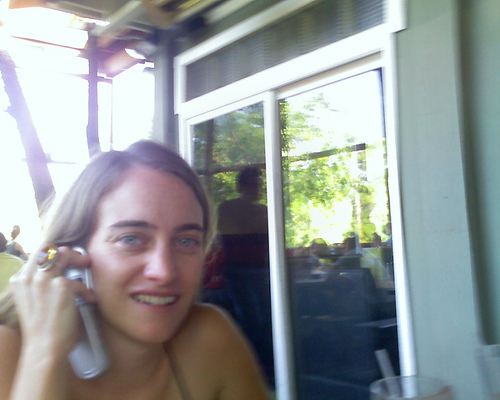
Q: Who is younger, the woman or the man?
A: The woman is younger than the man.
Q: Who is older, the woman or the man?
A: The man is older than the woman.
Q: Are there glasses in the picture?
A: No, there are no glasses.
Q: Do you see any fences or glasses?
A: No, there are no glasses or fences.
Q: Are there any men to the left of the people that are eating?
A: Yes, there is a man to the left of the people.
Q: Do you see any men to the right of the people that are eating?
A: No, the man is to the left of the people.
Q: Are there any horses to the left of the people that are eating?
A: No, there is a man to the left of the people.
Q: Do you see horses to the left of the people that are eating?
A: No, there is a man to the left of the people.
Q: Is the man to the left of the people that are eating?
A: Yes, the man is to the left of the people.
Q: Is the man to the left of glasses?
A: No, the man is to the left of the people.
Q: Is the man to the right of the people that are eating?
A: No, the man is to the left of the people.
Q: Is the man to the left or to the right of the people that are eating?
A: The man is to the left of the people.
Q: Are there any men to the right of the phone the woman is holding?
A: Yes, there is a man to the right of the phone.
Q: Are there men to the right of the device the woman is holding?
A: Yes, there is a man to the right of the phone.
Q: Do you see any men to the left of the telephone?
A: No, the man is to the right of the telephone.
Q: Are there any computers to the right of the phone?
A: No, there is a man to the right of the phone.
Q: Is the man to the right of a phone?
A: Yes, the man is to the right of a phone.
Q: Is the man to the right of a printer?
A: No, the man is to the right of a phone.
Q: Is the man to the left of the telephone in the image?
A: No, the man is to the right of the telephone.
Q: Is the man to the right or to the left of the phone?
A: The man is to the right of the phone.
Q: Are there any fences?
A: No, there are no fences.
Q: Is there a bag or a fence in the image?
A: No, there are no fences or bags.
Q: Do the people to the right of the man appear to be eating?
A: Yes, the people are eating.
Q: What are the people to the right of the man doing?
A: The people are eating.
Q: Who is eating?
A: The people are eating.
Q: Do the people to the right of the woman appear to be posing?
A: No, the people are eating.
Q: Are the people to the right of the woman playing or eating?
A: The people are eating.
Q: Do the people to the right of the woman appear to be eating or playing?
A: The people are eating.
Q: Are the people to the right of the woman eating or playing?
A: The people are eating.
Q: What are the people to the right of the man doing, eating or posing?
A: The people are eating.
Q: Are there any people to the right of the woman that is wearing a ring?
A: Yes, there are people to the right of the woman.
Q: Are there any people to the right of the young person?
A: Yes, there are people to the right of the woman.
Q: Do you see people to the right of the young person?
A: Yes, there are people to the right of the woman.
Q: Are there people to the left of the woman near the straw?
A: No, the people are to the right of the woman.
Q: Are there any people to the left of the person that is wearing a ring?
A: No, the people are to the right of the woman.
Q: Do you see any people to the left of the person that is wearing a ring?
A: No, the people are to the right of the woman.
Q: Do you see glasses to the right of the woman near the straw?
A: No, there are people to the right of the woman.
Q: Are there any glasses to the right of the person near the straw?
A: No, there are people to the right of the woman.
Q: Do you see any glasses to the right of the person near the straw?
A: No, there are people to the right of the woman.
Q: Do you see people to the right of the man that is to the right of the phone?
A: Yes, there are people to the right of the man.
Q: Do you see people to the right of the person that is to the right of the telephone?
A: Yes, there are people to the right of the man.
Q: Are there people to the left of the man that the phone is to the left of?
A: No, the people are to the right of the man.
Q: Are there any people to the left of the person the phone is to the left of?
A: No, the people are to the right of the man.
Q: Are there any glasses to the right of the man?
A: No, there are people to the right of the man.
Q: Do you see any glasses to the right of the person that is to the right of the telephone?
A: No, there are people to the right of the man.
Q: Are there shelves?
A: No, there are no shelves.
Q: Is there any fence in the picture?
A: No, there are no fences.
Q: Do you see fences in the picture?
A: No, there are no fences.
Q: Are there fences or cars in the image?
A: No, there are no fences or cars.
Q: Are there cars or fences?
A: No, there are no fences or cars.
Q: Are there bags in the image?
A: No, there are no bags.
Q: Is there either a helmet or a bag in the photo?
A: No, there are no bags or helmets.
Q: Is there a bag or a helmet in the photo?
A: No, there are no bags or helmets.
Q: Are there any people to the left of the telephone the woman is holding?
A: Yes, there is a person to the left of the phone.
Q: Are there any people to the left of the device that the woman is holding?
A: Yes, there is a person to the left of the phone.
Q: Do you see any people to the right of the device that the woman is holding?
A: No, the person is to the left of the phone.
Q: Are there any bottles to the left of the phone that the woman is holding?
A: No, there is a person to the left of the phone.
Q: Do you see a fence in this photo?
A: No, there are no fences.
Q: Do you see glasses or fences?
A: No, there are no fences or glasses.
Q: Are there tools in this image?
A: No, there are no tools.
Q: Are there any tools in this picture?
A: No, there are no tools.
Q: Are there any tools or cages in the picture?
A: No, there are no tools or cages.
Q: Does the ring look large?
A: Yes, the ring is large.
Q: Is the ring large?
A: Yes, the ring is large.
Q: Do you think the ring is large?
A: Yes, the ring is large.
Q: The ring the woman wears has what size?
A: The ring is large.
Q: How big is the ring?
A: The ring is large.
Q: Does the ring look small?
A: No, the ring is large.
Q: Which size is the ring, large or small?
A: The ring is large.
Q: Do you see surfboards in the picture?
A: No, there are no surfboards.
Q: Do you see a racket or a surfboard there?
A: No, there are no surfboards or rackets.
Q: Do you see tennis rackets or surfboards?
A: No, there are no surfboards or tennis rackets.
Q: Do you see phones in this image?
A: Yes, there is a phone.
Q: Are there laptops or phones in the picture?
A: Yes, there is a phone.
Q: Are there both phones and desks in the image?
A: No, there is a phone but no desks.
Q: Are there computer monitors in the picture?
A: No, there are no computer monitors.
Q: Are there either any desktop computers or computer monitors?
A: No, there are no computer monitors or desktop computers.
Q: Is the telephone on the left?
A: Yes, the telephone is on the left of the image.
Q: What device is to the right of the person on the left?
A: The device is a phone.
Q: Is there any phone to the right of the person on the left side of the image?
A: Yes, there is a phone to the right of the person.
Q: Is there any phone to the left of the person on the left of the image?
A: No, the phone is to the right of the person.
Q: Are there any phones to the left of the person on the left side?
A: No, the phone is to the right of the person.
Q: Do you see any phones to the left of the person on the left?
A: No, the phone is to the right of the person.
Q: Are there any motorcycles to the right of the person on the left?
A: No, there is a phone to the right of the person.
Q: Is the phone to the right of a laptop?
A: No, the phone is to the right of the person.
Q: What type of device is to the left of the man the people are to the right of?
A: The device is a phone.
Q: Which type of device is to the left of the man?
A: The device is a phone.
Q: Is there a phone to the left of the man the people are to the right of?
A: Yes, there is a phone to the left of the man.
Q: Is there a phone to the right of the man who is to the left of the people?
A: No, the phone is to the left of the man.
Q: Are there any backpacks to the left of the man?
A: No, there is a phone to the left of the man.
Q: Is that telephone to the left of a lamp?
A: No, the telephone is to the left of the man.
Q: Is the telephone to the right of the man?
A: No, the telephone is to the left of the man.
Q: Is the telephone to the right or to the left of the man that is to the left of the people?
A: The telephone is to the left of the man.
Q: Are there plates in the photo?
A: No, there are no plates.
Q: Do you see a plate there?
A: No, there are no plates.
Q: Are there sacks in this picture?
A: No, there are no sacks.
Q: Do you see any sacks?
A: No, there are no sacks.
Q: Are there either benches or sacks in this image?
A: No, there are no sacks or benches.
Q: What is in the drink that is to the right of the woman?
A: The straw is in the drink.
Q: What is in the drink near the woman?
A: The straw is in the drink.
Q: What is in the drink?
A: The straw is in the drink.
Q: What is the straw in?
A: The straw is in the drink.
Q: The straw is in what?
A: The straw is in the drink.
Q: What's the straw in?
A: The straw is in the drink.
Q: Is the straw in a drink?
A: Yes, the straw is in a drink.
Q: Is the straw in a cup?
A: No, the straw is in a drink.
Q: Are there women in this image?
A: Yes, there is a woman.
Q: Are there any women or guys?
A: Yes, there is a woman.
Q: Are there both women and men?
A: Yes, there are both a woman and a man.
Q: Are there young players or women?
A: Yes, there is a young woman.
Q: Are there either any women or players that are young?
A: Yes, the woman is young.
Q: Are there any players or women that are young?
A: Yes, the woman is young.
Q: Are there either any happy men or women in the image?
A: Yes, there is a happy woman.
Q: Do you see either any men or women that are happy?
A: Yes, the woman is happy.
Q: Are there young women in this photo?
A: Yes, there is a young woman.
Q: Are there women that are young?
A: Yes, there is a woman that is young.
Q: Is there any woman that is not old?
A: Yes, there is an young woman.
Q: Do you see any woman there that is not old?
A: Yes, there is an young woman.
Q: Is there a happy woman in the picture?
A: Yes, there is a happy woman.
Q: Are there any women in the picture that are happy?
A: Yes, there is a woman that is happy.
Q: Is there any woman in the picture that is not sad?
A: Yes, there is a happy woman.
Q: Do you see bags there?
A: No, there are no bags.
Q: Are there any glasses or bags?
A: No, there are no bags or glasses.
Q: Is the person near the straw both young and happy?
A: Yes, the woman is young and happy.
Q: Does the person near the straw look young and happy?
A: Yes, the woman is young and happy.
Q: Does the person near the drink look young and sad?
A: No, the woman is young but happy.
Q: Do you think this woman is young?
A: Yes, the woman is young.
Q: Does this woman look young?
A: Yes, the woman is young.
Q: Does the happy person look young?
A: Yes, the woman is young.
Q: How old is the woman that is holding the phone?
A: The woman is young.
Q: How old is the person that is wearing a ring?
A: The woman is young.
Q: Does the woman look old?
A: No, the woman is young.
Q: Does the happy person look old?
A: No, the woman is young.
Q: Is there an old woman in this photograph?
A: No, there is a woman but she is young.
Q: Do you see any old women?
A: No, there is a woman but she is young.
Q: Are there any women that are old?
A: No, there is a woman but she is young.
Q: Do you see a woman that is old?
A: No, there is a woman but she is young.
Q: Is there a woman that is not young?
A: No, there is a woman but she is young.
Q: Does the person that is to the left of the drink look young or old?
A: The woman is young.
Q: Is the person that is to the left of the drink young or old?
A: The woman is young.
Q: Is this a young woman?
A: Yes, this is a young woman.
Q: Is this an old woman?
A: No, this is a young woman.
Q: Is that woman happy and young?
A: Yes, the woman is happy and young.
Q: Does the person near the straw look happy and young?
A: Yes, the woman is happy and young.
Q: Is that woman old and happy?
A: No, the woman is happy but young.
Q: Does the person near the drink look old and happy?
A: No, the woman is happy but young.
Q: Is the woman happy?
A: Yes, the woman is happy.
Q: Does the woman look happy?
A: Yes, the woman is happy.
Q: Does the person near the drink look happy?
A: Yes, the woman is happy.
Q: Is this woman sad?
A: No, the woman is happy.